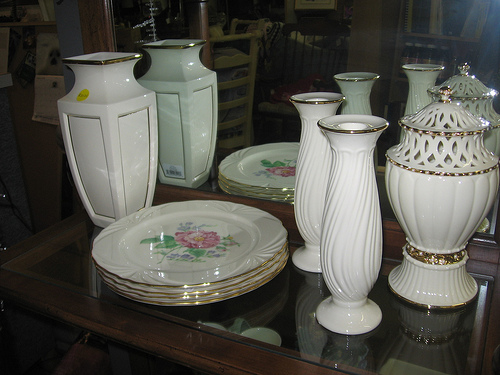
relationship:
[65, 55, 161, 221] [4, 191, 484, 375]
vase on table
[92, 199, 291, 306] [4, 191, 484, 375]
plates on table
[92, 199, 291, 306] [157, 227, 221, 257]
plates have floral pattern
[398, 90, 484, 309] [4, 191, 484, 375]
container on table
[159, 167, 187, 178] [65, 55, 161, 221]
bar code on vase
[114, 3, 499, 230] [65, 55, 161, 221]
mirror behind vase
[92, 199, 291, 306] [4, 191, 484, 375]
plates stacked on table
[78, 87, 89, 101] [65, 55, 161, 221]
sticker on vase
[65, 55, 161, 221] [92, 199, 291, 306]
vase beside plates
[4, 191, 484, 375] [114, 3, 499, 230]
table in front of mirror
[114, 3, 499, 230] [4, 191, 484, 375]
mirror behind table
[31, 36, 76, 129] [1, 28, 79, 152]
calendar hanging on wall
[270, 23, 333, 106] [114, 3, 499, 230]
chair reflected in mirror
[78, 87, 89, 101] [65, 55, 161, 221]
sticker on side of vase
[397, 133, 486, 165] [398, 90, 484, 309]
design on vase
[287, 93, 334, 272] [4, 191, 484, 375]
vase on top of table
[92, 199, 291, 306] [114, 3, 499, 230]
plates in front of mirror